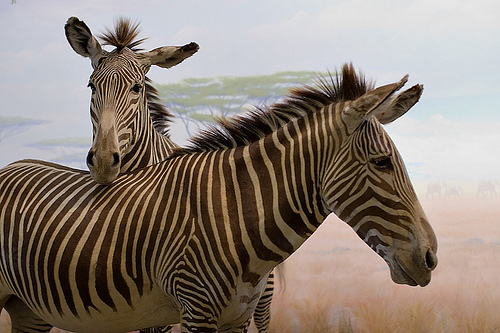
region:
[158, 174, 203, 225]
black and white stripes ona zebra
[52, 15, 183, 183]
face of a zebra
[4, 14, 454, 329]
two zebras together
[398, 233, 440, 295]
grey nose on a zebra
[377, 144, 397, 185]
black eye on a zebra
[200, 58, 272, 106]
hazy tree top in the background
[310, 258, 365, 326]
hazy scrubby grass behind the zebra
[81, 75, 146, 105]
eyes on a zebra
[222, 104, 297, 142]
white and black mane on a zebra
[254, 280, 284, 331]
hind leg on a zebra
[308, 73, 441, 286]
Head of a brown and white zebra that is pointing right.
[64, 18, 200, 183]
Brown and white stripes of a zebra with its head over another zebra.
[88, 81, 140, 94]
Black eyes of a brown and white zebra behind the close one.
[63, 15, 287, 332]
A brown and white zebra behind a close zebra.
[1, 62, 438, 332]
The most visible brown and white striped zebra.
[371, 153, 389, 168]
One visible eye of this zebra.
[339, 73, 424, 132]
Two ears pointing forward on this zebra.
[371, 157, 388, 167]
Black eye on the zebra pointing right.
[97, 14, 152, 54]
Black hair between the ears of the furthest zebra.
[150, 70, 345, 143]
The tree tops of a distant large tree.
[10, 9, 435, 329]
the zebras are two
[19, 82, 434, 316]
the zebra is black and white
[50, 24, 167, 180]
the zebra is black and white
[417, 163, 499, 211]
animals are in the background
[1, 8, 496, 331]
the animals are in africa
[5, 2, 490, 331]
the animals are in a tropical continent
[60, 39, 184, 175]
the zebra is looking at the camera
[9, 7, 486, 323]
the scene was taken during the day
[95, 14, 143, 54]
hair is on the head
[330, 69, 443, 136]
the ears are pointy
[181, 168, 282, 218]
black and white stripes on a zebra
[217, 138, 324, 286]
thick neck of a zebra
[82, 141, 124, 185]
two nostrils on a zebra's nose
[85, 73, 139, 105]
two eyes on a zebra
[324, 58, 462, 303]
profile view of a zebra head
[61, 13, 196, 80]
two ears on a zebra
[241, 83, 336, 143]
spikey short zebra mane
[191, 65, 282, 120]
pale colored tree behind the zebras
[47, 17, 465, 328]
a pair of zebras in a field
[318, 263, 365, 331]
brown colored ground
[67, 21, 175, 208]
face of the zebra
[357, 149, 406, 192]
eye of the zebra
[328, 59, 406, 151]
ear of the zebra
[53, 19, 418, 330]
two zebras standing in road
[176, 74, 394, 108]
hairs of the zebra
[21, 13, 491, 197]
a clear view of sky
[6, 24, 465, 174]
a beautiful view of sky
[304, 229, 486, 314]
a beautiful red grass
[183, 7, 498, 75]
a white sky with clouds